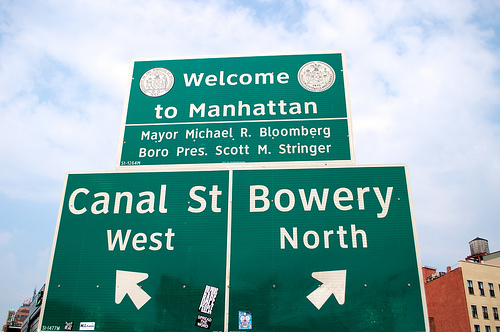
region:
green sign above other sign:
[120, 53, 363, 161]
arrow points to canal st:
[49, 157, 222, 327]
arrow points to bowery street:
[238, 166, 419, 330]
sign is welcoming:
[117, 53, 365, 161]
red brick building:
[407, 263, 474, 328]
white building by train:
[451, 234, 498, 321]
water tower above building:
[444, 242, 498, 258]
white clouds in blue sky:
[40, 21, 460, 193]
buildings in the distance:
[3, 291, 52, 330]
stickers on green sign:
[182, 271, 247, 326]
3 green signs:
[35, 42, 440, 327]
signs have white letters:
[37, 48, 433, 327]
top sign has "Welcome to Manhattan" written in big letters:
[120, 52, 366, 167]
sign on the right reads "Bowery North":
[238, 176, 403, 330]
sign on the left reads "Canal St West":
[62, 166, 222, 264]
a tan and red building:
[422, 248, 497, 328]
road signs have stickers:
[32, 272, 263, 328]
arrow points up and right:
[282, 252, 380, 319]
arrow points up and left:
[95, 253, 170, 314]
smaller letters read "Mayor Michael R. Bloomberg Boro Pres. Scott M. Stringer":
[128, 121, 351, 167]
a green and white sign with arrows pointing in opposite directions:
[32, 154, 440, 330]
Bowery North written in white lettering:
[240, 177, 405, 258]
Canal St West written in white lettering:
[60, 175, 227, 266]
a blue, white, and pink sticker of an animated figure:
[233, 302, 255, 330]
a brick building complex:
[412, 231, 499, 329]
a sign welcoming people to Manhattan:
[108, 45, 363, 169]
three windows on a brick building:
[462, 275, 498, 300]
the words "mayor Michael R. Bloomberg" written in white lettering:
[135, 123, 342, 143]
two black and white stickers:
[189, 274, 222, 329]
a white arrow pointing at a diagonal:
[300, 258, 358, 317]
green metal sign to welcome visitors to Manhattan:
[111, 49, 356, 158]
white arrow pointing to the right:
[288, 257, 366, 310]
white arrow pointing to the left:
[107, 267, 185, 316]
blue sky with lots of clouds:
[372, 20, 477, 154]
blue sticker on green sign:
[231, 305, 263, 329]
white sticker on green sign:
[192, 275, 220, 322]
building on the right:
[430, 227, 497, 327]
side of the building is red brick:
[422, 267, 470, 325]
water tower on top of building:
[466, 228, 492, 272]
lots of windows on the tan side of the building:
[451, 254, 493, 326]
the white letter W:
[182, 69, 207, 89]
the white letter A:
[136, 182, 156, 218]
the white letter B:
[241, 175, 271, 216]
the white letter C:
[64, 177, 98, 215]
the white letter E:
[330, 181, 353, 211]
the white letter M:
[139, 126, 152, 141]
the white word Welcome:
[177, 73, 289, 88]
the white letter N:
[271, 214, 299, 256]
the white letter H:
[349, 220, 373, 257]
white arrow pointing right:
[302, 255, 357, 313]